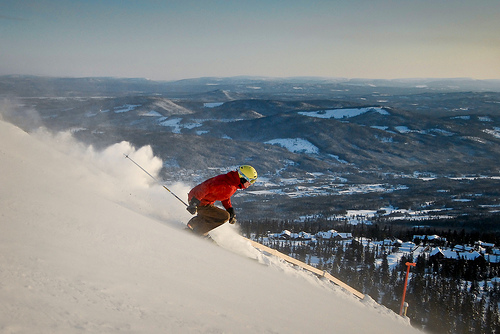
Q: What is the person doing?
A: Skiing.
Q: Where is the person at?
A: Ski resort.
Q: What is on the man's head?
A: Helmet.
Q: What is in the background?
A: Mountains.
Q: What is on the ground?
A: Snow.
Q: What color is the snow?
A: White.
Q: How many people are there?
A: One.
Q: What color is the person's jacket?
A: Red.